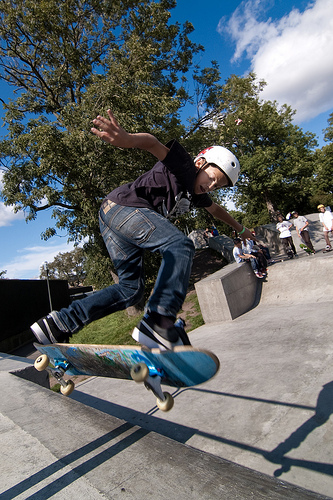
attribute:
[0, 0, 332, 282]
sky — blue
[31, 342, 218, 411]
skateboard — blue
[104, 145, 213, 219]
tee shirt —  blue,  cotton,  tee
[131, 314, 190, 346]
shoe — black, white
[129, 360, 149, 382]
tire —  gray,  plastic, for skate board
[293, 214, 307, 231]
grey shirt —  gray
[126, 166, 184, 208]
shirt — brown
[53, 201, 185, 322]
jeans —  medium blue ,  denim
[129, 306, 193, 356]
shoe — black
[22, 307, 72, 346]
shoe — black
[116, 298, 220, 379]
sneaker —  black and white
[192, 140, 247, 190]
helmet — white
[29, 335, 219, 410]
skate board — blue and gray, to skate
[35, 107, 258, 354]
man — light skinned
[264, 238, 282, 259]
ramp — far